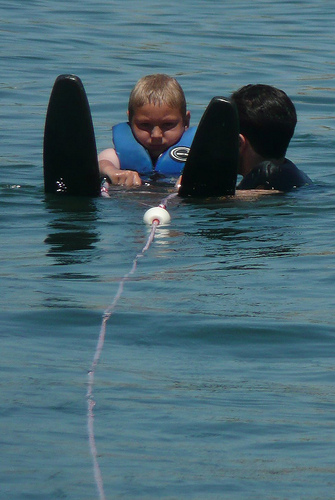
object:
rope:
[85, 221, 157, 499]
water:
[0, 0, 334, 498]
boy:
[97, 70, 203, 188]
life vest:
[111, 122, 197, 192]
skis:
[43, 72, 103, 201]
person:
[222, 83, 312, 194]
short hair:
[230, 81, 297, 158]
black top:
[253, 155, 307, 187]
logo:
[171, 143, 194, 164]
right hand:
[110, 167, 143, 192]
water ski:
[178, 95, 238, 203]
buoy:
[143, 207, 170, 227]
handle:
[138, 172, 174, 192]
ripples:
[234, 0, 335, 47]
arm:
[97, 145, 120, 173]